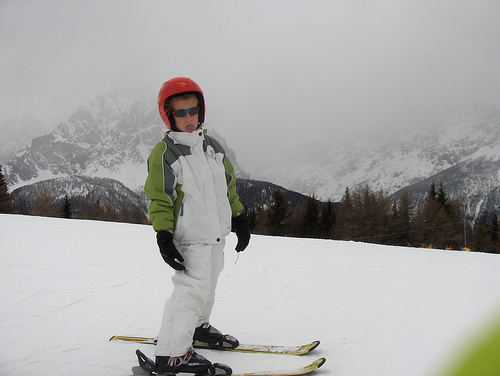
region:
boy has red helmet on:
[136, 63, 231, 143]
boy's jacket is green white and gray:
[127, 136, 279, 269]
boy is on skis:
[86, 44, 378, 374]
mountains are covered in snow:
[0, 59, 486, 294]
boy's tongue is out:
[178, 104, 205, 139]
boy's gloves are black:
[130, 205, 290, 279]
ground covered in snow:
[3, 213, 497, 370]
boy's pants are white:
[155, 241, 257, 364]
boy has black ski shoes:
[148, 309, 252, 374]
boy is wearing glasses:
[160, 101, 203, 119]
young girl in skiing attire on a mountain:
[107, 78, 326, 373]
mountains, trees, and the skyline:
[0, 0, 143, 224]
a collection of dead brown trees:
[249, 188, 499, 245]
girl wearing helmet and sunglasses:
[157, 79, 210, 134]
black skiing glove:
[153, 228, 191, 273]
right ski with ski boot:
[114, 352, 330, 374]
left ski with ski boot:
[105, 331, 319, 353]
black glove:
[232, 213, 254, 248]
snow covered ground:
[275, 260, 490, 335]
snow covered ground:
[3, 220, 107, 370]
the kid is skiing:
[125, 77, 315, 373]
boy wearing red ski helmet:
[149, 57, 231, 147]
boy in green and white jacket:
[129, 120, 259, 236]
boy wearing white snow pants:
[157, 214, 248, 374]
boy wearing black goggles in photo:
[160, 90, 212, 125]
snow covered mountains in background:
[6, 73, 497, 264]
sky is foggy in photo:
[5, 39, 478, 249]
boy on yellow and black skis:
[124, 307, 444, 374]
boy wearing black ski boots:
[132, 291, 265, 373]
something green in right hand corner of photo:
[428, 286, 498, 374]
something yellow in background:
[409, 208, 496, 279]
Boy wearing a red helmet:
[148, 72, 224, 131]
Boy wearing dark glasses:
[166, 105, 221, 121]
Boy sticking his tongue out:
[180, 120, 204, 135]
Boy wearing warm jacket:
[130, 127, 262, 234]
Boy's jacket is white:
[135, 127, 275, 244]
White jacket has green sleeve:
[138, 135, 190, 237]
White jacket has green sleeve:
[209, 140, 254, 214]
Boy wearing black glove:
[143, 224, 191, 272]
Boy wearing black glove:
[228, 204, 258, 258]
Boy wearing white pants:
[146, 227, 223, 364]